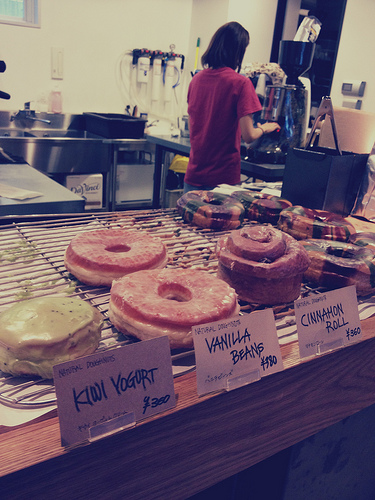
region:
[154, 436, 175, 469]
part of a board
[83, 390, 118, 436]
part of a paper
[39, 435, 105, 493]
edge of a wood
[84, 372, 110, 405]
part of a board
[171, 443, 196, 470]
part of a wood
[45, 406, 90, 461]
edge of a board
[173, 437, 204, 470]
part of a board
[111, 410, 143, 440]
part of a holder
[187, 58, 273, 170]
burgandy colored t- shirt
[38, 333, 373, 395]
three small white food sign cards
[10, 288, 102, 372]
green frosted kiwi donut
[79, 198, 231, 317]
two galzed pink donuts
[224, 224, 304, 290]
one cinnamon roll on tray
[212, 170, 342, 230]
swirl marble designed donut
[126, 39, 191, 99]
surge electrical outlet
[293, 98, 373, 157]
silver tongs in bucket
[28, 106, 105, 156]
silver large farm sink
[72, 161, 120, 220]
white box napkins papers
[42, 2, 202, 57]
The wall is white.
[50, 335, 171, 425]
Sign says kiwi yogurt.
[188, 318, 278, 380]
Sign says vanilla beans.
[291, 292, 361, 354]
Sign says cinnamon roll.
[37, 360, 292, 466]
The table is wooden.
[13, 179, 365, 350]
Doughnuts on a rack.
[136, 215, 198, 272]
Icing on the rack.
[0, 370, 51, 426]
Wax paper under the rack.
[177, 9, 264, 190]
Woman in the kitchen.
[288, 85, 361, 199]
Tongs in a box.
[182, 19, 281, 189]
a woman working in a bakery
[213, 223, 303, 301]
a large cinnamon roll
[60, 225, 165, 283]
a vanilla bean flavored doughnut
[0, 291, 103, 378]
a filled doughnut with frosting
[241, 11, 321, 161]
an industrial mixer made of steel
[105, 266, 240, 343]
a round pink doughnut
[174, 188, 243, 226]
a striped doughnut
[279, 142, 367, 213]
a dark colored box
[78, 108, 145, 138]
a black basin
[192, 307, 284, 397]
a sign selling vanilla bean doughnuts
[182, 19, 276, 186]
Person using restaurant equipment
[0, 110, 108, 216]
Large aluminum restaurant double sinks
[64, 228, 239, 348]
Two large Vanilla Bean donuts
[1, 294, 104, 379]
One Kiwi Yogurt donut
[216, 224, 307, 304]
One cinnamon roll on display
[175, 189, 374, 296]
Five very large flavored donuts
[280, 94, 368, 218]
Large salad tongs in a black container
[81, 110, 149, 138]
Black plastic dish pan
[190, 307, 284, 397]
White sales tag in a plastic holder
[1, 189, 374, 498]
Large wood table with aluminum grill rack